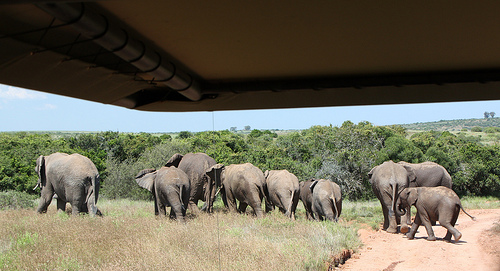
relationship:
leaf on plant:
[211, 137, 228, 159] [185, 125, 241, 155]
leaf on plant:
[11, 139, 54, 164] [18, 138, 58, 166]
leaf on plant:
[28, 129, 46, 149] [21, 131, 71, 155]